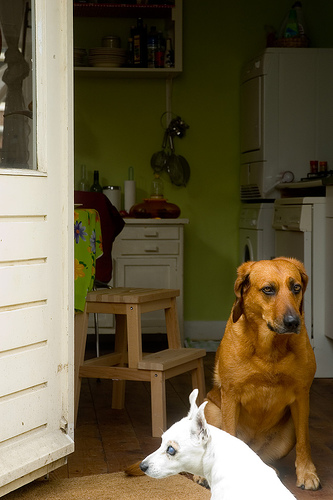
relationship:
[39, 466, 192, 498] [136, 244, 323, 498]
rug next dogs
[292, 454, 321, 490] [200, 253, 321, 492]
paw of a dog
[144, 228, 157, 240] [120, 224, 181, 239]
handle of drawer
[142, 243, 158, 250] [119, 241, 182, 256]
handle of drawer